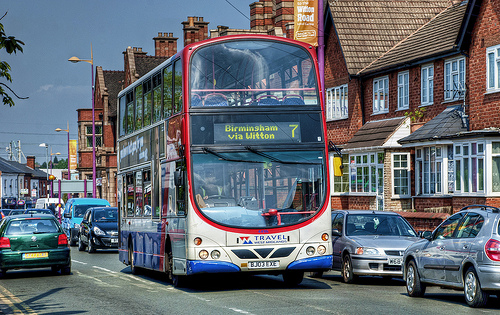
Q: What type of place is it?
A: It is a street.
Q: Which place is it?
A: It is a street.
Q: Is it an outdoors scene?
A: Yes, it is outdoors.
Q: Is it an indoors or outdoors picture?
A: It is outdoors.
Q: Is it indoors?
A: No, it is outdoors.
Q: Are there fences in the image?
A: No, there are no fences.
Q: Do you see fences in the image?
A: No, there are no fences.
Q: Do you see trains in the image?
A: No, there are no trains.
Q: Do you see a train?
A: No, there are no trains.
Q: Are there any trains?
A: No, there are no trains.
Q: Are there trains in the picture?
A: No, there are no trains.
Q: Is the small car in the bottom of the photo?
A: Yes, the car is in the bottom of the image.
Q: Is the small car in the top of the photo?
A: No, the car is in the bottom of the image.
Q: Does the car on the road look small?
A: Yes, the car is small.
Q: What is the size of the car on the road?
A: The car is small.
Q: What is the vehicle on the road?
A: The vehicle is a car.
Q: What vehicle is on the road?
A: The vehicle is a car.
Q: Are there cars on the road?
A: Yes, there is a car on the road.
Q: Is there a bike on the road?
A: No, there is a car on the road.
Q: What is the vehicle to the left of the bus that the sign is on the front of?
A: The vehicle is a car.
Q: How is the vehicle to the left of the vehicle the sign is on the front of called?
A: The vehicle is a car.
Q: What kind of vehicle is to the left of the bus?
A: The vehicle is a car.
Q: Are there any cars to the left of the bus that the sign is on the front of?
A: Yes, there is a car to the left of the bus.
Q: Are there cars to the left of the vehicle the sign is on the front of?
A: Yes, there is a car to the left of the bus.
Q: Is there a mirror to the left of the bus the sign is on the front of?
A: No, there is a car to the left of the bus.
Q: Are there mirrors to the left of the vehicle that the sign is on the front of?
A: No, there is a car to the left of the bus.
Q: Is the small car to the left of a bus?
A: Yes, the car is to the left of a bus.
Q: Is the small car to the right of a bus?
A: No, the car is to the left of a bus.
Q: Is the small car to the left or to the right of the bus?
A: The car is to the left of the bus.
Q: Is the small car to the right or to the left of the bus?
A: The car is to the left of the bus.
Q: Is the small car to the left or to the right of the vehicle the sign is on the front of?
A: The car is to the left of the bus.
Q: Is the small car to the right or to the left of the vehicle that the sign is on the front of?
A: The car is to the left of the bus.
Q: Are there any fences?
A: No, there are no fences.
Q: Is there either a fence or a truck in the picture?
A: No, there are no fences or trucks.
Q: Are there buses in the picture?
A: Yes, there is a bus.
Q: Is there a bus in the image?
A: Yes, there is a bus.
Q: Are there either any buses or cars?
A: Yes, there is a bus.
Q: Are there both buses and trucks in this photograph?
A: No, there is a bus but no trucks.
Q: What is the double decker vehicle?
A: The vehicle is a bus.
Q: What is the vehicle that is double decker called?
A: The vehicle is a bus.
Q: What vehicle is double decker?
A: The vehicle is a bus.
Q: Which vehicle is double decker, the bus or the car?
A: The bus is double decker.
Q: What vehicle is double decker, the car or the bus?
A: The bus is double decker.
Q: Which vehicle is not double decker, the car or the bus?
A: The car is not double decker.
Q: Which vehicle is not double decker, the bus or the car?
A: The car is not double decker.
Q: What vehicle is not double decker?
A: The vehicle is a car.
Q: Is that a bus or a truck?
A: That is a bus.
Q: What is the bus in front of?
A: The bus is in front of the car.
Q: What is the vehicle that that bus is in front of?
A: The vehicle is a car.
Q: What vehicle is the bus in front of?
A: The bus is in front of the car.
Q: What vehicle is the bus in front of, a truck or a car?
A: The bus is in front of a car.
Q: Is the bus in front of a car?
A: Yes, the bus is in front of a car.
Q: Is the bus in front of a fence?
A: No, the bus is in front of a car.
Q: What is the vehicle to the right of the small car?
A: The vehicle is a bus.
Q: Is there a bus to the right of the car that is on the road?
A: Yes, there is a bus to the right of the car.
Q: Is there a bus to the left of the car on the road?
A: No, the bus is to the right of the car.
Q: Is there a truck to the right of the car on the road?
A: No, there is a bus to the right of the car.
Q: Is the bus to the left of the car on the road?
A: No, the bus is to the right of the car.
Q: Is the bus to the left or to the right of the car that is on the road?
A: The bus is to the right of the car.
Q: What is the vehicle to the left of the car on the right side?
A: The vehicle is a bus.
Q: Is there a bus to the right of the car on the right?
A: No, the bus is to the left of the car.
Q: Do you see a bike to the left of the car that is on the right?
A: No, there is a bus to the left of the car.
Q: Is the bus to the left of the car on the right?
A: Yes, the bus is to the left of the car.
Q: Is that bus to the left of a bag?
A: No, the bus is to the left of the car.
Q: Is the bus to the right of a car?
A: No, the bus is to the left of a car.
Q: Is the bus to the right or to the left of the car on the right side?
A: The bus is to the left of the car.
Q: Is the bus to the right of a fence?
A: No, the bus is to the right of the car.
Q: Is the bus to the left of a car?
A: No, the bus is to the right of a car.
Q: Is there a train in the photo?
A: No, there are no trains.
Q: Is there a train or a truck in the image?
A: No, there are no trains or trucks.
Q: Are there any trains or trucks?
A: No, there are no trains or trucks.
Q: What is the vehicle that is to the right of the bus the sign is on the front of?
A: The vehicle is a car.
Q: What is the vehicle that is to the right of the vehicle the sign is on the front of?
A: The vehicle is a car.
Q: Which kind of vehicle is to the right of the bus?
A: The vehicle is a car.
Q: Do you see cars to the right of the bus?
A: Yes, there is a car to the right of the bus.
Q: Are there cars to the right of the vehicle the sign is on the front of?
A: Yes, there is a car to the right of the bus.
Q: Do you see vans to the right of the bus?
A: No, there is a car to the right of the bus.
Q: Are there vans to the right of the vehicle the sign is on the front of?
A: No, there is a car to the right of the bus.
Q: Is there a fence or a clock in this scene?
A: No, there are no fences or clocks.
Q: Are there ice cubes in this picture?
A: No, there are no ice cubes.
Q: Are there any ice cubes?
A: No, there are no ice cubes.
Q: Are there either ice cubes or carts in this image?
A: No, there are no ice cubes or carts.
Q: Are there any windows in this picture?
A: Yes, there is a window.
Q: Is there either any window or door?
A: Yes, there is a window.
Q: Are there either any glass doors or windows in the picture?
A: Yes, there is a glass window.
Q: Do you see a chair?
A: No, there are no chairs.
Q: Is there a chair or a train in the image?
A: No, there are no chairs or trains.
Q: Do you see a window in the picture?
A: Yes, there is a window.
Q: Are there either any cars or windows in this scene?
A: Yes, there is a window.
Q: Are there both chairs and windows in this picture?
A: No, there is a window but no chairs.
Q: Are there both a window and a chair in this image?
A: No, there is a window but no chairs.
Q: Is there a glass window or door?
A: Yes, there is a glass window.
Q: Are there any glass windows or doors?
A: Yes, there is a glass window.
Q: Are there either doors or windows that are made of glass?
A: Yes, the window is made of glass.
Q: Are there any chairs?
A: No, there are no chairs.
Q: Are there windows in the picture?
A: Yes, there is a window.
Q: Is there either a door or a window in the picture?
A: Yes, there is a window.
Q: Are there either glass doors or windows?
A: Yes, there is a glass window.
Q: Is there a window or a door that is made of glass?
A: Yes, the window is made of glass.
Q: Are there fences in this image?
A: No, there are no fences.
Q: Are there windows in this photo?
A: Yes, there is a window.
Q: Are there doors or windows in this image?
A: Yes, there is a window.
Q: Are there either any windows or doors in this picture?
A: Yes, there is a window.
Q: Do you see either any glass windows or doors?
A: Yes, there is a glass window.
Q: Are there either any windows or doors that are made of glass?
A: Yes, the window is made of glass.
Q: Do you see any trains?
A: No, there are no trains.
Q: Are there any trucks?
A: No, there are no trucks.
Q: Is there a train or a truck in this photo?
A: No, there are no trucks or trains.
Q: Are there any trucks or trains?
A: No, there are no trucks or trains.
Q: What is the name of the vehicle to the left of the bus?
A: The vehicle is a car.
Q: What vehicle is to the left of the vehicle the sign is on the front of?
A: The vehicle is a car.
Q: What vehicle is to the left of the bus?
A: The vehicle is a car.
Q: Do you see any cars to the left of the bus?
A: Yes, there is a car to the left of the bus.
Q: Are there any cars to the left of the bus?
A: Yes, there is a car to the left of the bus.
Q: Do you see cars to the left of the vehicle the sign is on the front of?
A: Yes, there is a car to the left of the bus.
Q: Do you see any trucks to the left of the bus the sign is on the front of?
A: No, there is a car to the left of the bus.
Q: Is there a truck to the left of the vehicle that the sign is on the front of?
A: No, there is a car to the left of the bus.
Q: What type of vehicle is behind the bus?
A: The vehicle is a car.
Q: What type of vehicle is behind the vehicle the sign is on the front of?
A: The vehicle is a car.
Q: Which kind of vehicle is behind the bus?
A: The vehicle is a car.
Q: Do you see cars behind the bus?
A: Yes, there is a car behind the bus.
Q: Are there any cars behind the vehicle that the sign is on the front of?
A: Yes, there is a car behind the bus.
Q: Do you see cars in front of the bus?
A: No, the car is behind the bus.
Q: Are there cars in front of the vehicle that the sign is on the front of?
A: No, the car is behind the bus.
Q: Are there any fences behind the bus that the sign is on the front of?
A: No, there is a car behind the bus.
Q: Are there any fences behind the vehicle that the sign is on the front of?
A: No, there is a car behind the bus.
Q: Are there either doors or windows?
A: Yes, there is a window.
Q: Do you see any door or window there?
A: Yes, there is a window.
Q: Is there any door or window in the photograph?
A: Yes, there is a window.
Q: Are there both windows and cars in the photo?
A: Yes, there are both a window and a car.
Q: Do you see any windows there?
A: Yes, there is a window.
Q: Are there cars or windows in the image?
A: Yes, there is a window.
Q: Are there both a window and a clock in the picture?
A: No, there is a window but no clocks.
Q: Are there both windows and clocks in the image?
A: No, there is a window but no clocks.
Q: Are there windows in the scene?
A: Yes, there is a window.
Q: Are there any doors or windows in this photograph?
A: Yes, there is a window.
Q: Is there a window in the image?
A: Yes, there is a window.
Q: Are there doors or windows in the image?
A: Yes, there is a window.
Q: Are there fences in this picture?
A: No, there are no fences.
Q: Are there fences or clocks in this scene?
A: No, there are no fences or clocks.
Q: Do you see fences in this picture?
A: No, there are no fences.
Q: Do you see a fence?
A: No, there are no fences.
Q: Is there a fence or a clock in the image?
A: No, there are no fences or clocks.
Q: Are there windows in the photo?
A: Yes, there is a window.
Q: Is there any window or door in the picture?
A: Yes, there is a window.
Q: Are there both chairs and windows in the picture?
A: No, there is a window but no chairs.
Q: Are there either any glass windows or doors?
A: Yes, there is a glass window.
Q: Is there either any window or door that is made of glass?
A: Yes, the window is made of glass.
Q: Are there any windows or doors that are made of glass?
A: Yes, the window is made of glass.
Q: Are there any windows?
A: Yes, there is a window.